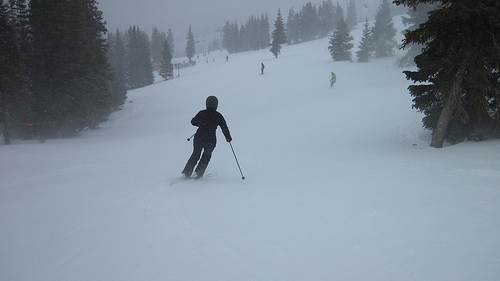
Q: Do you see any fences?
A: No, there are no fences.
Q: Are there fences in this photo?
A: No, there are no fences.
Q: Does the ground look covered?
A: Yes, the ground is covered.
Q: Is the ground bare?
A: No, the ground is covered.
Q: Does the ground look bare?
A: No, the ground is covered.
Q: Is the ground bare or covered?
A: The ground is covered.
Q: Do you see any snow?
A: Yes, there is snow.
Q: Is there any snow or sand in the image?
A: Yes, there is snow.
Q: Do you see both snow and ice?
A: No, there is snow but no ice.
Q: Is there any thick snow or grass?
A: Yes, there is thick snow.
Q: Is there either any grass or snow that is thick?
A: Yes, the snow is thick.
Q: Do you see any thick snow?
A: Yes, there is thick snow.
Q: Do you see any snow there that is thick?
A: Yes, there is snow that is thick.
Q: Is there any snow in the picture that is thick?
A: Yes, there is snow that is thick.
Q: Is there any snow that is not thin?
A: Yes, there is thick snow.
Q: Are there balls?
A: No, there are no balls.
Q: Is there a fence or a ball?
A: No, there are no balls or fences.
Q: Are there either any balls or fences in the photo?
A: No, there are no balls or fences.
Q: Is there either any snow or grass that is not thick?
A: No, there is snow but it is thick.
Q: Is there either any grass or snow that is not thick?
A: No, there is snow but it is thick.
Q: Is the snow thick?
A: Yes, the snow is thick.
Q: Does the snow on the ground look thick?
A: Yes, the snow is thick.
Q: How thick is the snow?
A: The snow is thick.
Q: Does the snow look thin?
A: No, the snow is thick.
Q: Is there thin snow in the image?
A: No, there is snow but it is thick.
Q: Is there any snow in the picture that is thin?
A: No, there is snow but it is thick.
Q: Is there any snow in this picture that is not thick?
A: No, there is snow but it is thick.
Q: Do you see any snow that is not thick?
A: No, there is snow but it is thick.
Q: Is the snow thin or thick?
A: The snow is thick.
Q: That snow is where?
A: The snow is on the ground.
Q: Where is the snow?
A: The snow is on the ground.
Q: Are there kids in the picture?
A: No, there are no kids.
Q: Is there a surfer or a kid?
A: No, there are no children or surfers.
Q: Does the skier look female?
A: Yes, the skier is female.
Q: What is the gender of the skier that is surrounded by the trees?
A: The skier is female.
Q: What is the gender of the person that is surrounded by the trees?
A: The skier is female.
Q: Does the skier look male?
A: No, the skier is female.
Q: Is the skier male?
A: No, the skier is female.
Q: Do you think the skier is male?
A: No, the skier is female.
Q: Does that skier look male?
A: No, the skier is female.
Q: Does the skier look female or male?
A: The skier is female.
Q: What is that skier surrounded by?
A: The skier is surrounded by the trees.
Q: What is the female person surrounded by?
A: The skier is surrounded by the trees.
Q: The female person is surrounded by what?
A: The skier is surrounded by the trees.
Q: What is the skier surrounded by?
A: The skier is surrounded by the trees.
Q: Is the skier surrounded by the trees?
A: Yes, the skier is surrounded by the trees.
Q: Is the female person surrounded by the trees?
A: Yes, the skier is surrounded by the trees.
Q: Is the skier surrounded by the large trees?
A: Yes, the skier is surrounded by the trees.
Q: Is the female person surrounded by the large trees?
A: Yes, the skier is surrounded by the trees.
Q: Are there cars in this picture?
A: No, there are no cars.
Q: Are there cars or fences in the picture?
A: No, there are no cars or fences.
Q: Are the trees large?
A: Yes, the trees are large.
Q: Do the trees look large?
A: Yes, the trees are large.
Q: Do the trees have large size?
A: Yes, the trees are large.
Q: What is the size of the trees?
A: The trees are large.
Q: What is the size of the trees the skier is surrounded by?
A: The trees are large.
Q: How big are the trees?
A: The trees are large.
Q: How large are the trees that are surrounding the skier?
A: The trees are large.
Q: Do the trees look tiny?
A: No, the trees are large.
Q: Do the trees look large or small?
A: The trees are large.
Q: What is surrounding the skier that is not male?
A: The trees are surrounding the skier.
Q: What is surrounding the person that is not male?
A: The trees are surrounding the skier.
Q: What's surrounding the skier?
A: The trees are surrounding the skier.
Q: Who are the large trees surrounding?
A: The trees are surrounding the skier.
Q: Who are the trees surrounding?
A: The trees are surrounding the skier.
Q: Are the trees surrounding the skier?
A: Yes, the trees are surrounding the skier.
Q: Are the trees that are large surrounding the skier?
A: Yes, the trees are surrounding the skier.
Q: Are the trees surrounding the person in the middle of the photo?
A: Yes, the trees are surrounding the skier.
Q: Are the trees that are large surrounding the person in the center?
A: Yes, the trees are surrounding the skier.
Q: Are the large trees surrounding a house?
A: No, the trees are surrounding the skier.